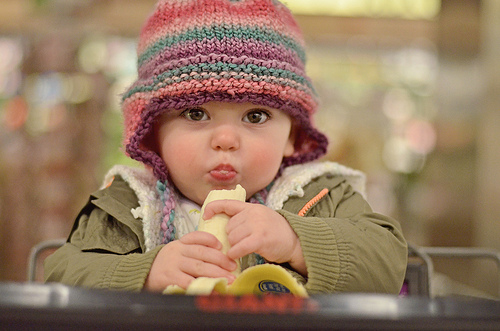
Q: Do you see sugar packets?
A: No, there are no sugar packets.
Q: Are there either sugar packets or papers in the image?
A: No, there are no sugar packets or papers.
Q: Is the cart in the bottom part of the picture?
A: Yes, the cart is in the bottom of the image.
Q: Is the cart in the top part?
A: No, the cart is in the bottom of the image.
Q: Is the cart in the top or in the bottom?
A: The cart is in the bottom of the image.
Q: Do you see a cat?
A: No, there are no cats.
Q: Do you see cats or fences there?
A: No, there are no cats or fences.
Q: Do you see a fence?
A: No, there are no fences.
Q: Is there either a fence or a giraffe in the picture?
A: No, there are no fences or giraffes.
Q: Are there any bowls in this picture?
A: No, there are no bowls.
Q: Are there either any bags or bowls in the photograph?
A: No, there are no bowls or bags.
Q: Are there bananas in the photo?
A: Yes, there is a banana.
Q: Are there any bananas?
A: Yes, there is a banana.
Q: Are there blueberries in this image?
A: No, there are no blueberries.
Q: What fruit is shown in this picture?
A: The fruit is a banana.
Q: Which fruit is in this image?
A: The fruit is a banana.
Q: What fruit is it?
A: The fruit is a banana.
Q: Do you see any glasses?
A: No, there are no glasses.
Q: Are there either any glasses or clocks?
A: No, there are no glasses or clocks.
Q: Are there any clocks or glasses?
A: No, there are no glasses or clocks.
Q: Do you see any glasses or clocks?
A: No, there are no glasses or clocks.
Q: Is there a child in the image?
A: Yes, there is a child.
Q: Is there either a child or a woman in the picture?
A: Yes, there is a child.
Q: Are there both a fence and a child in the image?
A: No, there is a child but no fences.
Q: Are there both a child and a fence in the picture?
A: No, there is a child but no fences.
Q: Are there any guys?
A: No, there are no guys.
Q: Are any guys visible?
A: No, there are no guys.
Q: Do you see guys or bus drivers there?
A: No, there are no guys or bus drivers.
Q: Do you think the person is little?
A: Yes, the child is little.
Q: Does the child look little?
A: Yes, the child is little.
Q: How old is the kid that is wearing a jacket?
A: The child is little.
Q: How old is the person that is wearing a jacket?
A: The child is little.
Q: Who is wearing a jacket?
A: The child is wearing a jacket.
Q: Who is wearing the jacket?
A: The child is wearing a jacket.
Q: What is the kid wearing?
A: The kid is wearing a jacket.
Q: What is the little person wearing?
A: The kid is wearing a jacket.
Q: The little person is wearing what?
A: The kid is wearing a jacket.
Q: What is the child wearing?
A: The kid is wearing a jacket.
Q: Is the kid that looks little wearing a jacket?
A: Yes, the kid is wearing a jacket.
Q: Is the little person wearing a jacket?
A: Yes, the kid is wearing a jacket.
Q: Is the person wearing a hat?
A: No, the child is wearing a jacket.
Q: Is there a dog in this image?
A: No, there are no dogs.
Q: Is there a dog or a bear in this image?
A: No, there are no dogs or bears.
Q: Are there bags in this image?
A: No, there are no bags.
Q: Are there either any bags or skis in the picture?
A: No, there are no bags or skis.